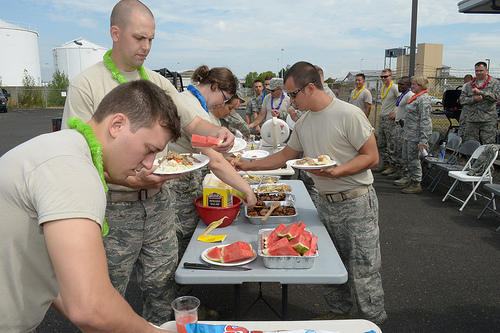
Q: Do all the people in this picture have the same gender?
A: No, they are both male and female.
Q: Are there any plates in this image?
A: Yes, there is a plate.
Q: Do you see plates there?
A: Yes, there is a plate.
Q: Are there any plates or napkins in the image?
A: Yes, there is a plate.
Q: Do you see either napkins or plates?
A: Yes, there is a plate.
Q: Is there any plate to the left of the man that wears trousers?
A: Yes, there is a plate to the left of the man.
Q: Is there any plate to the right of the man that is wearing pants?
A: No, the plate is to the left of the man.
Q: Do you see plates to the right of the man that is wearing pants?
A: No, the plate is to the left of the man.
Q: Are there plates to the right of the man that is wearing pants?
A: No, the plate is to the left of the man.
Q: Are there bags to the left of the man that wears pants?
A: No, there is a plate to the left of the man.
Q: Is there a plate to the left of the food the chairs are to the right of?
A: Yes, there is a plate to the left of the food.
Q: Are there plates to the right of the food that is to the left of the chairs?
A: No, the plate is to the left of the food.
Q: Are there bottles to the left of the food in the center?
A: No, there is a plate to the left of the food.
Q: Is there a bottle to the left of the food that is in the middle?
A: No, there is a plate to the left of the food.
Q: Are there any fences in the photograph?
A: Yes, there is a fence.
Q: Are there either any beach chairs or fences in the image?
A: Yes, there is a fence.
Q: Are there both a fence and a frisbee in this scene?
A: No, there is a fence but no frisbees.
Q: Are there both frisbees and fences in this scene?
A: No, there is a fence but no frisbees.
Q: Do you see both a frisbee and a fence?
A: No, there is a fence but no frisbees.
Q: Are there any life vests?
A: No, there are no life vests.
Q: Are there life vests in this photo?
A: No, there are no life vests.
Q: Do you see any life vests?
A: No, there are no life vests.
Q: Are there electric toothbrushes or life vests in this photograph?
A: No, there are no life vests or electric toothbrushes.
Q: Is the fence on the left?
A: Yes, the fence is on the left of the image.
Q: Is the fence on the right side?
A: No, the fence is on the left of the image.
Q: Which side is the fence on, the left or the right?
A: The fence is on the left of the image.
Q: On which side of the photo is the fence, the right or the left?
A: The fence is on the left of the image.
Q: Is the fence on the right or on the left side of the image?
A: The fence is on the left of the image.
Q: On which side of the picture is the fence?
A: The fence is on the left of the image.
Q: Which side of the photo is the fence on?
A: The fence is on the left of the image.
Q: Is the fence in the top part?
A: Yes, the fence is in the top of the image.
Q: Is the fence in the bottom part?
A: No, the fence is in the top of the image.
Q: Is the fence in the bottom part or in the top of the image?
A: The fence is in the top of the image.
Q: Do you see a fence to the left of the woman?
A: Yes, there is a fence to the left of the woman.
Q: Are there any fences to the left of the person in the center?
A: Yes, there is a fence to the left of the woman.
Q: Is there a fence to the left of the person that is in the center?
A: Yes, there is a fence to the left of the woman.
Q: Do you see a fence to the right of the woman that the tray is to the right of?
A: No, the fence is to the left of the woman.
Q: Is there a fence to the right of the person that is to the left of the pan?
A: No, the fence is to the left of the woman.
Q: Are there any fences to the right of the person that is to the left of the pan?
A: No, the fence is to the left of the woman.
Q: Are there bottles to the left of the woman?
A: No, there is a fence to the left of the woman.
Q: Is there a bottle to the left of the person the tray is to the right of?
A: No, there is a fence to the left of the woman.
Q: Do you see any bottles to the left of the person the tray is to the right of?
A: No, there is a fence to the left of the woman.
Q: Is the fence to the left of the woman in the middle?
A: Yes, the fence is to the left of the woman.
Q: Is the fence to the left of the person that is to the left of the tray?
A: Yes, the fence is to the left of the woman.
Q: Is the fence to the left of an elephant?
A: No, the fence is to the left of the woman.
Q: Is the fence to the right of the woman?
A: No, the fence is to the left of the woman.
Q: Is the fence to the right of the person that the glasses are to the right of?
A: No, the fence is to the left of the woman.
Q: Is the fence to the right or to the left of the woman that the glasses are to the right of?
A: The fence is to the left of the woman.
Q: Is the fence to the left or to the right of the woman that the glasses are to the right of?
A: The fence is to the left of the woman.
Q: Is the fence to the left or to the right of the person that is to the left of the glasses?
A: The fence is to the left of the woman.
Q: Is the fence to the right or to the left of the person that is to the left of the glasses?
A: The fence is to the left of the woman.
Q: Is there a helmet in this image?
A: No, there are no helmets.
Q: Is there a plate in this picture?
A: Yes, there is a plate.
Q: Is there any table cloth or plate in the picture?
A: Yes, there is a plate.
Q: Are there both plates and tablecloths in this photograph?
A: No, there is a plate but no tablecloths.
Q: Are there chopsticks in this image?
A: No, there are no chopsticks.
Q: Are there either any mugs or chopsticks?
A: No, there are no chopsticks or mugs.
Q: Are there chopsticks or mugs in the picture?
A: No, there are no chopsticks or mugs.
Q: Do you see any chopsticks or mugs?
A: No, there are no chopsticks or mugs.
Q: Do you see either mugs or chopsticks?
A: No, there are no chopsticks or mugs.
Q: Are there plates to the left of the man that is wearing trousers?
A: Yes, there is a plate to the left of the man.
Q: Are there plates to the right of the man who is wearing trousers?
A: No, the plate is to the left of the man.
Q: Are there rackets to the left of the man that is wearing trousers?
A: No, there is a plate to the left of the man.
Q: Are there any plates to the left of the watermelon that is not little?
A: Yes, there is a plate to the left of the watermelon.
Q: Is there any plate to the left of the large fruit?
A: Yes, there is a plate to the left of the watermelon.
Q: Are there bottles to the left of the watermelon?
A: No, there is a plate to the left of the watermelon.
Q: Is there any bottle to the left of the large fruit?
A: No, there is a plate to the left of the watermelon.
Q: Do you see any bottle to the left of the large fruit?
A: No, there is a plate to the left of the watermelon.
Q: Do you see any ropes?
A: No, there are no ropes.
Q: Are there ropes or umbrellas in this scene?
A: No, there are no ropes or umbrellas.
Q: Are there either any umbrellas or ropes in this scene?
A: No, there are no ropes or umbrellas.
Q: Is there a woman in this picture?
A: Yes, there is a woman.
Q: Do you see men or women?
A: Yes, there is a woman.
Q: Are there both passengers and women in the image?
A: No, there is a woman but no passengers.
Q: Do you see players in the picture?
A: No, there are no players.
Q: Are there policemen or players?
A: No, there are no players or policemen.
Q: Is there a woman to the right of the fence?
A: Yes, there is a woman to the right of the fence.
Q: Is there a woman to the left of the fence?
A: No, the woman is to the right of the fence.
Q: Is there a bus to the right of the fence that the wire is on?
A: No, there is a woman to the right of the fence.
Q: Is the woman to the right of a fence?
A: Yes, the woman is to the right of a fence.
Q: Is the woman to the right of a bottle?
A: No, the woman is to the right of a fence.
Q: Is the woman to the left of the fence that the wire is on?
A: No, the woman is to the right of the fence.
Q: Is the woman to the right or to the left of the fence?
A: The woman is to the right of the fence.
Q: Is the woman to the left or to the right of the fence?
A: The woman is to the right of the fence.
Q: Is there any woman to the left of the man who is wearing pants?
A: Yes, there is a woman to the left of the man.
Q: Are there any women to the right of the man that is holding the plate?
A: No, the woman is to the left of the man.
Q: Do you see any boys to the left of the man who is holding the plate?
A: No, there is a woman to the left of the man.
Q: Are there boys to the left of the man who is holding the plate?
A: No, there is a woman to the left of the man.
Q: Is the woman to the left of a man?
A: Yes, the woman is to the left of a man.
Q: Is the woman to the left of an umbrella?
A: No, the woman is to the left of a man.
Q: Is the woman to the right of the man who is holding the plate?
A: No, the woman is to the left of the man.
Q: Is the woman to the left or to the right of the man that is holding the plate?
A: The woman is to the left of the man.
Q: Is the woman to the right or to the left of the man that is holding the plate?
A: The woman is to the left of the man.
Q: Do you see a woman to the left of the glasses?
A: Yes, there is a woman to the left of the glasses.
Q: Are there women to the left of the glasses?
A: Yes, there is a woman to the left of the glasses.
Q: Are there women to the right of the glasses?
A: No, the woman is to the left of the glasses.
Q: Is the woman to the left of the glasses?
A: Yes, the woman is to the left of the glasses.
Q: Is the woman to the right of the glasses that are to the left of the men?
A: No, the woman is to the left of the glasses.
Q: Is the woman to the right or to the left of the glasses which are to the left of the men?
A: The woman is to the left of the glasses.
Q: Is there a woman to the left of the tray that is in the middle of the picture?
A: Yes, there is a woman to the left of the tray.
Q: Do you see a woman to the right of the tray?
A: No, the woman is to the left of the tray.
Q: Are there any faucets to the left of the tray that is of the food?
A: No, there is a woman to the left of the tray.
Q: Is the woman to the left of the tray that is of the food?
A: Yes, the woman is to the left of the tray.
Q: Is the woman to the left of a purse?
A: No, the woman is to the left of the tray.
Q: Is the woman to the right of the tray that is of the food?
A: No, the woman is to the left of the tray.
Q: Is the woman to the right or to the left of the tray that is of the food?
A: The woman is to the left of the tray.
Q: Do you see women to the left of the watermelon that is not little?
A: Yes, there is a woman to the left of the watermelon.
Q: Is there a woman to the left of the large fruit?
A: Yes, there is a woman to the left of the watermelon.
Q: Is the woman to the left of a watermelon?
A: Yes, the woman is to the left of a watermelon.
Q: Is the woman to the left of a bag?
A: No, the woman is to the left of a watermelon.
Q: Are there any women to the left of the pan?
A: Yes, there is a woman to the left of the pan.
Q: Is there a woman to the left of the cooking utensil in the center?
A: Yes, there is a woman to the left of the pan.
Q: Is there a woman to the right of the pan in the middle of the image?
A: No, the woman is to the left of the pan.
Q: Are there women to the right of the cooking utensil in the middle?
A: No, the woman is to the left of the pan.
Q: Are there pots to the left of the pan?
A: No, there is a woman to the left of the pan.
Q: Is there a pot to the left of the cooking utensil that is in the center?
A: No, there is a woman to the left of the pan.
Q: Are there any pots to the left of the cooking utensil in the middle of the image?
A: No, there is a woman to the left of the pan.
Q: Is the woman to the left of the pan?
A: Yes, the woman is to the left of the pan.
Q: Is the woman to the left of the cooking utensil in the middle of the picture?
A: Yes, the woman is to the left of the pan.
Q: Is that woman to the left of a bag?
A: No, the woman is to the left of the pan.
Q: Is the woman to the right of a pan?
A: No, the woman is to the left of a pan.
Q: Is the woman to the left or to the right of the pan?
A: The woman is to the left of the pan.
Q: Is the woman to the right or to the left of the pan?
A: The woman is to the left of the pan.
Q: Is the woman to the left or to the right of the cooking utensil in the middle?
A: The woman is to the left of the pan.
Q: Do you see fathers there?
A: No, there are no fathers.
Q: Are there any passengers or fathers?
A: No, there are no fathers or passengers.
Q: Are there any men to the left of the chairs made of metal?
A: Yes, there are men to the left of the chairs.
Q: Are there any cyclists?
A: No, there are no cyclists.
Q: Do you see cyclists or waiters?
A: No, there are no cyclists or waiters.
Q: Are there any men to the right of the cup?
A: Yes, there is a man to the right of the cup.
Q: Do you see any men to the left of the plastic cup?
A: No, the man is to the right of the cup.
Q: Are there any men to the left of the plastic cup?
A: No, the man is to the right of the cup.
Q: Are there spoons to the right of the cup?
A: No, there is a man to the right of the cup.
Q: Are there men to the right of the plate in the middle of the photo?
A: Yes, there is a man to the right of the plate.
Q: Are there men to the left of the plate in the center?
A: No, the man is to the right of the plate.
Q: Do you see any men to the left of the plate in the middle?
A: No, the man is to the right of the plate.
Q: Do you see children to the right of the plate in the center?
A: No, there is a man to the right of the plate.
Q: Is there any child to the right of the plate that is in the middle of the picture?
A: No, there is a man to the right of the plate.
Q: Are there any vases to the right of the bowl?
A: No, there is a man to the right of the bowl.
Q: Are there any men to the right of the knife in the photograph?
A: Yes, there is a man to the right of the knife.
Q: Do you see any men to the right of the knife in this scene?
A: Yes, there is a man to the right of the knife.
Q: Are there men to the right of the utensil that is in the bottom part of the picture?
A: Yes, there is a man to the right of the knife.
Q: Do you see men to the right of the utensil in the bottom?
A: Yes, there is a man to the right of the knife.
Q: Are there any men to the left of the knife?
A: No, the man is to the right of the knife.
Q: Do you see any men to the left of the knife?
A: No, the man is to the right of the knife.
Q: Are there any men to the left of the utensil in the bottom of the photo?
A: No, the man is to the right of the knife.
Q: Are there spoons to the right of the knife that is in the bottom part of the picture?
A: No, there is a man to the right of the knife.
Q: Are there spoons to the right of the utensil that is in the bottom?
A: No, there is a man to the right of the knife.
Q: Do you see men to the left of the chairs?
A: Yes, there is a man to the left of the chairs.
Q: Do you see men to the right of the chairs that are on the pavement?
A: No, the man is to the left of the chairs.